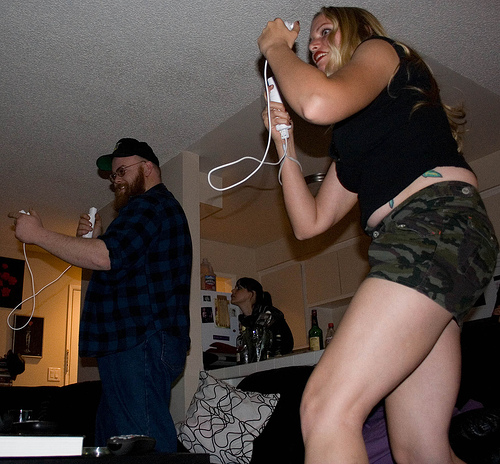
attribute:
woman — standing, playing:
[305, 13, 496, 359]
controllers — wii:
[241, 12, 335, 127]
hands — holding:
[235, 13, 340, 64]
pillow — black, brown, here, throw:
[217, 340, 267, 458]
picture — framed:
[3, 301, 85, 380]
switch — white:
[28, 326, 84, 400]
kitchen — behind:
[226, 262, 391, 380]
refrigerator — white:
[208, 283, 230, 350]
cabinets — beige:
[273, 268, 359, 315]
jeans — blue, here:
[101, 340, 207, 432]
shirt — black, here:
[326, 76, 485, 204]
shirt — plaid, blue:
[113, 187, 222, 304]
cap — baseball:
[58, 122, 145, 176]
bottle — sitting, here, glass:
[279, 295, 357, 354]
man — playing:
[109, 151, 147, 178]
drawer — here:
[294, 266, 358, 298]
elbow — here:
[285, 190, 327, 244]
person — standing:
[58, 126, 173, 363]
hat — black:
[99, 137, 204, 174]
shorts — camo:
[385, 205, 493, 288]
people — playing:
[97, 49, 491, 378]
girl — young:
[270, 13, 437, 182]